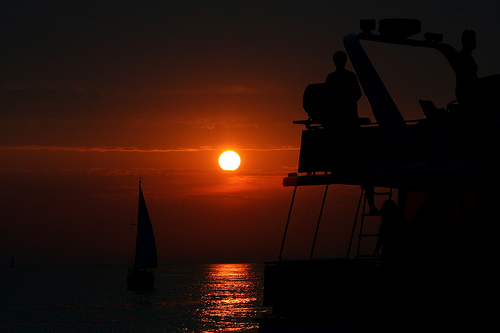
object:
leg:
[364, 186, 375, 208]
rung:
[360, 212, 382, 216]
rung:
[364, 192, 393, 196]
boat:
[253, 17, 500, 320]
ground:
[379, 160, 408, 185]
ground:
[411, 145, 459, 196]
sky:
[0, 0, 500, 268]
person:
[456, 30, 479, 80]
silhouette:
[363, 186, 379, 214]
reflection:
[193, 261, 272, 333]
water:
[0, 260, 499, 332]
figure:
[322, 50, 362, 126]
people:
[315, 49, 364, 128]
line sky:
[0, 133, 302, 160]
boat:
[124, 169, 161, 295]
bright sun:
[218, 150, 241, 171]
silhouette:
[325, 50, 362, 130]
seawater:
[192, 256, 265, 329]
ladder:
[346, 184, 394, 259]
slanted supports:
[278, 184, 366, 261]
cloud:
[4, 91, 301, 169]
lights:
[357, 17, 443, 46]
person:
[375, 198, 400, 257]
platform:
[297, 125, 500, 174]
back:
[264, 16, 500, 314]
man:
[361, 184, 381, 217]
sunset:
[35, 79, 295, 245]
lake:
[0, 259, 500, 333]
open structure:
[281, 16, 500, 187]